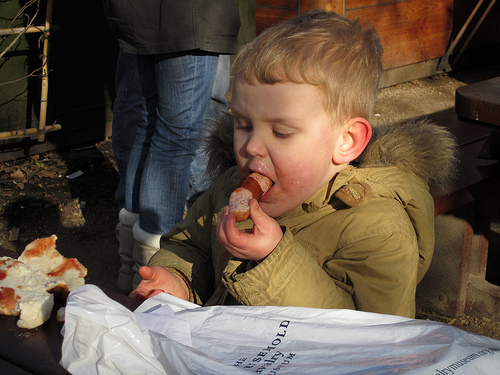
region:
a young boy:
[139, 10, 435, 315]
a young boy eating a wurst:
[135, 8, 437, 318]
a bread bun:
[3, 225, 85, 335]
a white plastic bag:
[65, 283, 499, 373]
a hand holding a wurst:
[214, 171, 289, 261]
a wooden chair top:
[417, 210, 499, 330]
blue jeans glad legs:
[123, 53, 213, 214]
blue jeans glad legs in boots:
[118, 44, 217, 263]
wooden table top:
[435, 54, 499, 130]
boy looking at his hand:
[188, 7, 380, 261]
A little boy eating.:
[133, 20, 430, 315]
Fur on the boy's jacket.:
[376, 123, 459, 200]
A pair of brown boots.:
[116, 208, 158, 300]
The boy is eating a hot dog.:
[216, 168, 289, 260]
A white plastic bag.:
[61, 293, 489, 374]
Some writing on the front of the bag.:
[233, 316, 295, 373]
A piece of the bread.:
[3, 238, 81, 326]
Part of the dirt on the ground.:
[18, 171, 61, 223]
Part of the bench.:
[445, 107, 497, 208]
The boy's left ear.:
[331, 115, 375, 167]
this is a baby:
[221, 53, 380, 257]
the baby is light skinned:
[291, 135, 329, 158]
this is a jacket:
[325, 213, 404, 298]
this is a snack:
[238, 173, 248, 208]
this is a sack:
[194, 324, 299, 371]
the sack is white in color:
[323, 328, 389, 370]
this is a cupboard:
[398, 18, 435, 47]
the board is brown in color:
[387, 10, 433, 42]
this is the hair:
[303, 25, 349, 64]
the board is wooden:
[391, 11, 442, 67]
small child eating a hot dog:
[146, 20, 417, 300]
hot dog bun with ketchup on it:
[19, 229, 80, 335]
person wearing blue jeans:
[118, 17, 219, 245]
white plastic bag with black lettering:
[100, 314, 465, 369]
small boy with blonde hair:
[221, 28, 401, 295]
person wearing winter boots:
[110, 188, 182, 291]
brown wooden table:
[15, 330, 56, 369]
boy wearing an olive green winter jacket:
[167, 15, 452, 312]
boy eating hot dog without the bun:
[214, 16, 371, 256]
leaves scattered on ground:
[11, 148, 106, 195]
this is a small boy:
[207, 24, 402, 304]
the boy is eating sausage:
[221, 166, 287, 221]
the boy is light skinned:
[278, 148, 313, 170]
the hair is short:
[256, 16, 363, 78]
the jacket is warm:
[323, 175, 420, 312]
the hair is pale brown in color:
[271, 22, 361, 74]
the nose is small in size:
[245, 135, 267, 156]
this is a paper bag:
[237, 319, 365, 374]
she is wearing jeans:
[128, 63, 205, 207]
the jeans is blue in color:
[140, 86, 181, 190]